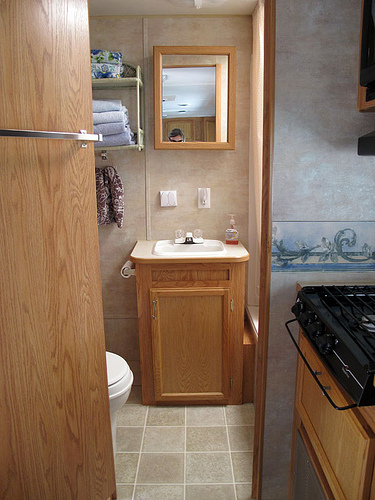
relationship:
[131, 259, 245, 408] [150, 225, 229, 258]
cabinet beneath sink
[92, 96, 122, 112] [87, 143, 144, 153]
towel on shelf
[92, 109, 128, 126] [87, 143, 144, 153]
towel on shelf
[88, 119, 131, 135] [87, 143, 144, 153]
towel on shelf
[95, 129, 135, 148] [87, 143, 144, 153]
towel on shelf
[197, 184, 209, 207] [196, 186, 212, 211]
nightlight plugged into outlet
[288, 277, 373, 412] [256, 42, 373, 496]
stove top near wall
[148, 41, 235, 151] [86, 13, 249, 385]
mirror attached to wall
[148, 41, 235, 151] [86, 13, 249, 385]
mirror on wall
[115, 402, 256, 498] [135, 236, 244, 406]
floor below cabinet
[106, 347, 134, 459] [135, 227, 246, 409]
toilet next to sink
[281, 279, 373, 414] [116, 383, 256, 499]
stove above floor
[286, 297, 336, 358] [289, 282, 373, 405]
knobs on stove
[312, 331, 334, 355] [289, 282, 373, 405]
knob on stove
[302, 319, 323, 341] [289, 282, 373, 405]
knob on stove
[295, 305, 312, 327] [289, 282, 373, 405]
knob on stove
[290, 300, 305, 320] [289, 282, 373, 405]
knob on stove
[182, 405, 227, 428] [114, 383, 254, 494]
tile on floor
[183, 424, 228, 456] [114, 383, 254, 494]
tile on floor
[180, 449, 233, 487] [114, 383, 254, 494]
tile on floor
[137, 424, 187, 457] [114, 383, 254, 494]
tile on floor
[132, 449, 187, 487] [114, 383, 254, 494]
tile on floor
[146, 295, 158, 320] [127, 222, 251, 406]
handle on cabinet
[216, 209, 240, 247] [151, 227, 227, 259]
soap next to sink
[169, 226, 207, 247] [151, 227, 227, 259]
faucet on sink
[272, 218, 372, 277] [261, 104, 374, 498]
design on wall